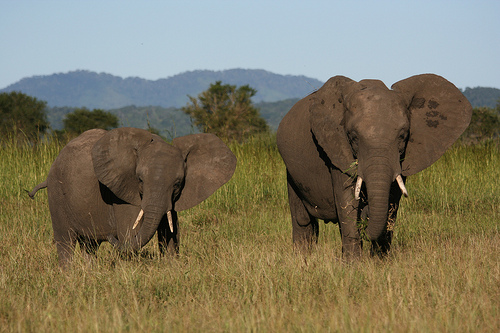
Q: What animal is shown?
A: Elephants.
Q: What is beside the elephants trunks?
A: Tusks.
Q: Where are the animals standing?
A: In the grass.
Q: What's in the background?
A: Trees.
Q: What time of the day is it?
A: Afternoon.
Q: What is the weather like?
A: Sunny.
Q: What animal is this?
A: Elephant.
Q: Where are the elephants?
A: Grassy field.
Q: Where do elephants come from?
A: Africa.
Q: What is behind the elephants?
A: Trees.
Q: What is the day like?
A: Sunny.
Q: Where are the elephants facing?
A: Forward.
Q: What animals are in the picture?
A: Elephants.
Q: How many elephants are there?
A: Two.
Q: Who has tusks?
A: Elephants.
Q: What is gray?
A: The elephants.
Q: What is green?
A: Grass.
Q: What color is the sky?
A: Blue.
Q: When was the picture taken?
A: Daytime.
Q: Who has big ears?
A: Two elephants.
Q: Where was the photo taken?
A: On the savannah.